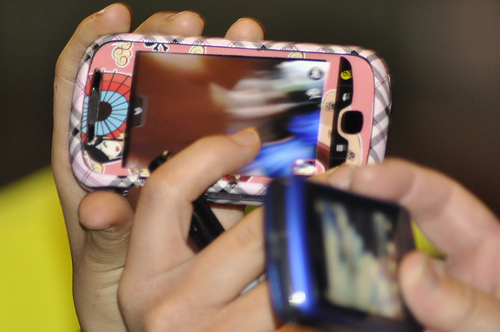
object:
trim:
[67, 31, 393, 198]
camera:
[264, 176, 424, 332]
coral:
[131, 52, 328, 177]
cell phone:
[65, 20, 392, 209]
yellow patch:
[1, 0, 500, 329]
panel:
[317, 53, 370, 168]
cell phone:
[67, 32, 393, 206]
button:
[340, 71, 352, 80]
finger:
[398, 252, 497, 332]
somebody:
[0, 2, 497, 329]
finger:
[224, 16, 264, 42]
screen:
[119, 49, 328, 180]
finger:
[76, 190, 133, 265]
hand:
[351, 157, 500, 332]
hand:
[117, 127, 356, 332]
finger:
[50, 3, 130, 251]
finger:
[131, 10, 205, 37]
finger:
[351, 157, 498, 250]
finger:
[127, 126, 262, 268]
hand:
[49, 0, 390, 331]